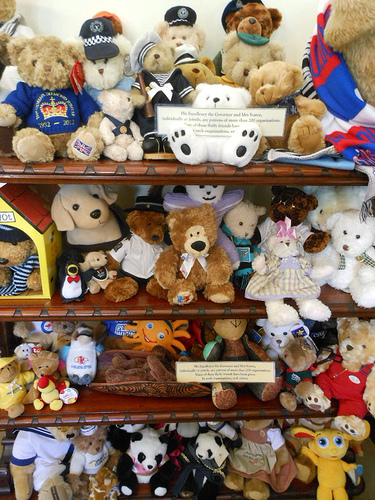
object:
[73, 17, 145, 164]
stuffed animals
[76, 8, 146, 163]
animals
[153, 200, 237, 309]
teddy bear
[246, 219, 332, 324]
rabbit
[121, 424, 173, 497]
panda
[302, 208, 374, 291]
bear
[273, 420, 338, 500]
plush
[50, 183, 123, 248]
dog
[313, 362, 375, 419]
overalls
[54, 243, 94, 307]
penguin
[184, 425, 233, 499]
bear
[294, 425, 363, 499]
bunny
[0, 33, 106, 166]
toy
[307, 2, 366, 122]
scarf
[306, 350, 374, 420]
coveralls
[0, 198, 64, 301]
box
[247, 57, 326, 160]
toys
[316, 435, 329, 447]
eyes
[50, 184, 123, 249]
doggie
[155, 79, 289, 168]
polar bear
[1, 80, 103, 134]
shirt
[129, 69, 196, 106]
dress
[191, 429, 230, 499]
pandas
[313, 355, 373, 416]
jumpsuit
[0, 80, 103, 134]
outfit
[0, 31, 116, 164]
bear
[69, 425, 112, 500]
stuffed toy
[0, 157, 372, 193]
shelf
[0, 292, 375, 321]
shelf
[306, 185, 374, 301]
stuffed animals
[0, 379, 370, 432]
shelf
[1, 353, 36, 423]
stuffed animals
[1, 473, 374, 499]
shelf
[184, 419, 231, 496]
stuffed animals